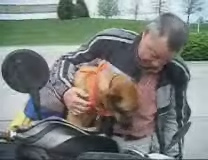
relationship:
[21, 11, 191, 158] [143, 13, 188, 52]
man has hair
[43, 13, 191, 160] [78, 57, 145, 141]
man holding dog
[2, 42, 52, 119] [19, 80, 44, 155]
mirror on bike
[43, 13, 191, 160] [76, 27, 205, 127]
man wearing coat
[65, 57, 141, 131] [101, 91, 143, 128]
brown dog has black nose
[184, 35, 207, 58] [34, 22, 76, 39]
bush across street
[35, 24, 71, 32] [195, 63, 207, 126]
grass across street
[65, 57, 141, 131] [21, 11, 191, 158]
brown dog sitting on man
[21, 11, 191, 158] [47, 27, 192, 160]
man wearing coat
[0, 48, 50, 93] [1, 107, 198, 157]
mirror on bike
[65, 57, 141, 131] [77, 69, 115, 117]
brown dog wearing bandanna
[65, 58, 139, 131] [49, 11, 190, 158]
brown dog on man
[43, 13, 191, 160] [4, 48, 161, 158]
man standing by motorcycle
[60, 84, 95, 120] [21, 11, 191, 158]
hand of man